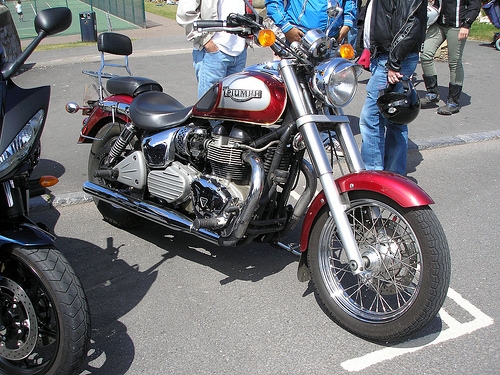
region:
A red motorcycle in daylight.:
[76, 21, 461, 336]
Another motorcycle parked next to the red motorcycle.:
[0, 15, 120, 370]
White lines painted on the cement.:
[325, 281, 495, 367]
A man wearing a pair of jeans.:
[170, 36, 260, 101]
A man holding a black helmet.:
[365, 70, 440, 132]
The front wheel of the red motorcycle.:
[295, 170, 460, 341]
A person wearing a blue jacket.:
[262, 0, 357, 51]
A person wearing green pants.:
[420, 20, 470, 80]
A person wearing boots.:
[416, 67, 463, 117]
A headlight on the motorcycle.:
[315, 55, 361, 113]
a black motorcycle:
[0, 0, 92, 362]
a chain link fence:
[0, 3, 144, 38]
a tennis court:
[0, 0, 83, 28]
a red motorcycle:
[83, 30, 433, 329]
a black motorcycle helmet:
[371, 70, 428, 123]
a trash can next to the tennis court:
[70, 3, 102, 46]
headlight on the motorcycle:
[310, 42, 365, 107]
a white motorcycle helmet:
[420, 0, 437, 32]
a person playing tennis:
[5, 0, 28, 23]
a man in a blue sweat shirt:
[262, 0, 366, 79]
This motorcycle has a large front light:
[320, 62, 372, 107]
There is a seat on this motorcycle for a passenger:
[85, 24, 155, 91]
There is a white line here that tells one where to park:
[364, 347, 390, 369]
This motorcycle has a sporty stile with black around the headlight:
[11, 82, 53, 164]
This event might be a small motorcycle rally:
[41, 7, 396, 346]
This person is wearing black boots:
[427, 65, 474, 132]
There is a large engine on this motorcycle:
[181, 53, 278, 233]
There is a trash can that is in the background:
[74, 6, 100, 49]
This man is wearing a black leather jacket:
[380, 8, 410, 55]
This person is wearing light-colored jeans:
[449, 52, 462, 67]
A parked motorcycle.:
[73, 26, 473, 338]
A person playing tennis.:
[5, 0, 27, 22]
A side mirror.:
[15, 0, 75, 72]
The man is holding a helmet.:
[345, 0, 425, 180]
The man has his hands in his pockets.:
[172, 0, 257, 97]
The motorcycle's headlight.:
[302, 46, 362, 126]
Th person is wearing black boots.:
[415, 66, 471, 117]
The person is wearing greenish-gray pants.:
[415, 25, 465, 80]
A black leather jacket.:
[355, 0, 425, 75]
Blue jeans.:
[191, 45, 251, 95]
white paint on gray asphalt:
[325, 337, 369, 373]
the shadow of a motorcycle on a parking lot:
[77, 243, 167, 373]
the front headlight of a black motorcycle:
[2, 99, 48, 188]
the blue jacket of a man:
[262, 0, 361, 52]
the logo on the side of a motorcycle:
[217, 77, 264, 107]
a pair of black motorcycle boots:
[419, 72, 462, 119]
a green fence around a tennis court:
[27, 2, 147, 32]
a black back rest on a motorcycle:
[92, 27, 133, 64]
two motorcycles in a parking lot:
[1, 0, 453, 369]